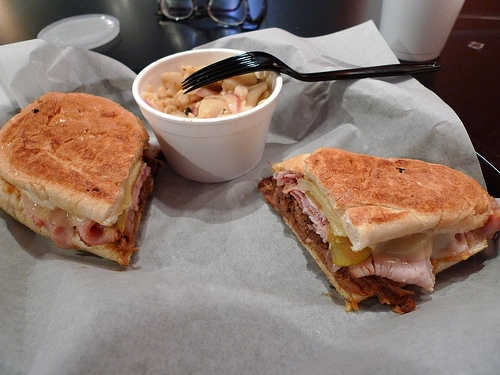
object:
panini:
[256, 146, 500, 315]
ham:
[275, 169, 500, 293]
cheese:
[303, 177, 432, 267]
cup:
[131, 46, 283, 183]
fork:
[180, 50, 444, 94]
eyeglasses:
[160, 0, 265, 26]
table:
[0, 0, 499, 375]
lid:
[37, 13, 120, 50]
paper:
[0, 19, 499, 375]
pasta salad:
[142, 64, 272, 118]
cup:
[379, 0, 467, 63]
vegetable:
[326, 226, 372, 267]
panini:
[0, 92, 161, 265]